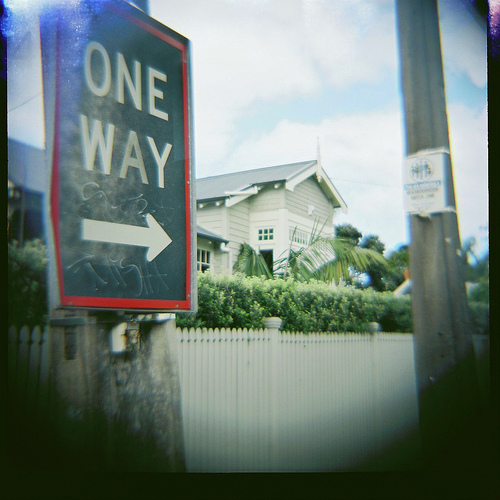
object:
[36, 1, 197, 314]
sign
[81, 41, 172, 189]
words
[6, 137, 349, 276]
house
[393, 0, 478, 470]
pole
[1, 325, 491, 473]
fence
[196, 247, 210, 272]
window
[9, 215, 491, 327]
bushes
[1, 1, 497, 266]
sky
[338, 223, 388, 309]
trees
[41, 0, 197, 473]
post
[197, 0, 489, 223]
clouds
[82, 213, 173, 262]
arrow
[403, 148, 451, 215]
poster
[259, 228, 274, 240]
window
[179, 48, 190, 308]
red line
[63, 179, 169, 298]
graffitti